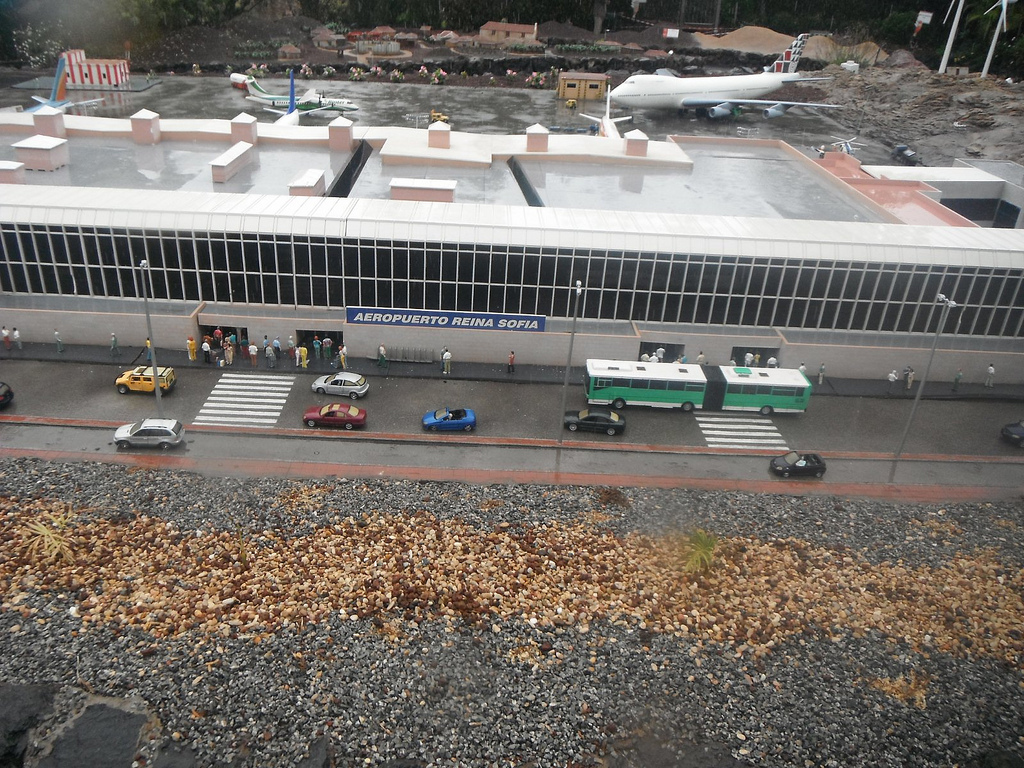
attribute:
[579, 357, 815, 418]
bus — green, white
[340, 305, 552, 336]
sign — blue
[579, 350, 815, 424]
bus — large, green, white, long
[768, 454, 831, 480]
sedan — black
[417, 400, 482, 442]
sedan — blue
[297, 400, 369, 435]
sedan — red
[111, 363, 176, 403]
hummer — yellow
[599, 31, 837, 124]
plane — large, white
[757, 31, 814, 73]
tail — red, green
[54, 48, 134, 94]
building — red, white, striped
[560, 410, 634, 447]
car — black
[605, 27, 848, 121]
airplane — white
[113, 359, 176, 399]
truck — yellow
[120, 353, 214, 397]
vehicle — yellow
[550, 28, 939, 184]
airplane — large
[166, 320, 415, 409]
people — gathered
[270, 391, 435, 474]
car — red, traveling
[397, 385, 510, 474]
car — moving, blue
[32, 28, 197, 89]
building — red, white, striped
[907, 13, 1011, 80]
turbines — white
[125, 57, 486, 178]
airplane — smaller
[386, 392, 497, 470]
car — blue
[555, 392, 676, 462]
car — black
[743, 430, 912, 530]
car — black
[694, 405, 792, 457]
lines — thick, white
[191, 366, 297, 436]
lines — white, thick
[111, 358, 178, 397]
hummer — yellow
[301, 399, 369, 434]
car — red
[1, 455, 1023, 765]
rocks — multi colored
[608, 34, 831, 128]
airplane — parked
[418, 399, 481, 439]
car — blue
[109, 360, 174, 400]
car — yellow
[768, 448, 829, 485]
car — black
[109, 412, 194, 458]
car — silver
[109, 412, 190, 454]
car — silver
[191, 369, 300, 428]
crosswalk — white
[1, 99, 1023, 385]
building — glass, large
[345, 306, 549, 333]
sign — white, blue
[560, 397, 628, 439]
car — black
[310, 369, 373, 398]
car — silver